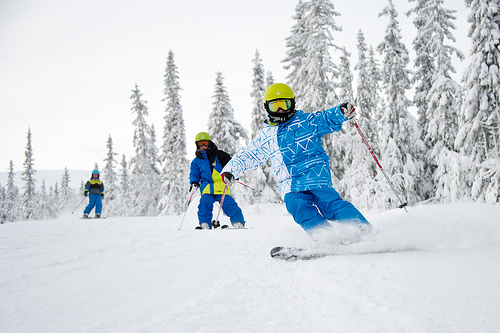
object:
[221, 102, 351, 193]
coat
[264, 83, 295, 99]
helmet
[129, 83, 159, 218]
tree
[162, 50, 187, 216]
tree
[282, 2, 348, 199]
tree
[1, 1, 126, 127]
sky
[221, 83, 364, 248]
kid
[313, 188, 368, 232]
leg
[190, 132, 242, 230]
child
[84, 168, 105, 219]
boy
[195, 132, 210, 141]
helmet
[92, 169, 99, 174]
helmet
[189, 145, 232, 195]
jacket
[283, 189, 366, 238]
pants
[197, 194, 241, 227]
pants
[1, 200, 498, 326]
snow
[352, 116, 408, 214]
ski pole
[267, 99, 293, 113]
goggles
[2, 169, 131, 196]
hill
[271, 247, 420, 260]
ski